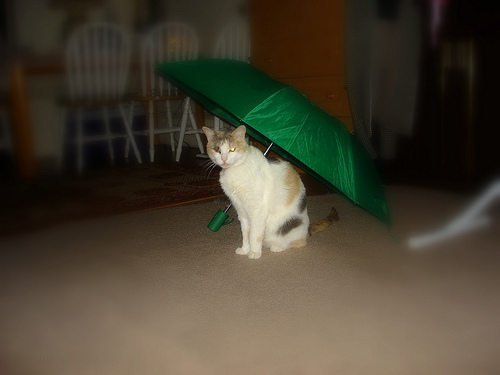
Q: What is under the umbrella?
A: Cat.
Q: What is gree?
A: Umbrella.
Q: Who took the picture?
A: Man.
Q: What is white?
A: Cat.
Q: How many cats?
A: One.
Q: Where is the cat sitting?
A: On the ground.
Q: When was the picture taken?
A: Nighttime.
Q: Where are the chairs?
A: Behind the cat.